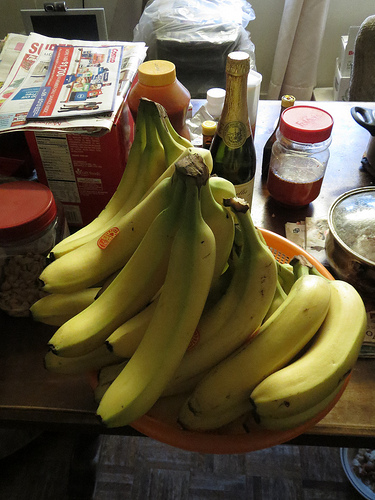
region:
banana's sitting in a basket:
[88, 191, 340, 397]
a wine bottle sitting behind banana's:
[205, 55, 254, 202]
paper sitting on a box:
[5, 87, 124, 135]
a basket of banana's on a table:
[256, 212, 361, 362]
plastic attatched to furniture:
[129, 12, 264, 55]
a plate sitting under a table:
[328, 454, 369, 494]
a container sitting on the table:
[306, 202, 360, 263]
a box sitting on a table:
[25, 139, 89, 188]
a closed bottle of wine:
[210, 51, 256, 211]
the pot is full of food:
[327, 187, 373, 286]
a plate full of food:
[337, 446, 373, 498]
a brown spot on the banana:
[280, 399, 289, 409]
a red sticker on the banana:
[96, 227, 119, 250]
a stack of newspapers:
[1, 33, 145, 135]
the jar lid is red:
[279, 105, 333, 140]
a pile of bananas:
[42, 98, 363, 428]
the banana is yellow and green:
[96, 181, 218, 424]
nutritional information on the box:
[33, 127, 81, 204]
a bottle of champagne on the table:
[215, 51, 256, 176]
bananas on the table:
[77, 124, 329, 411]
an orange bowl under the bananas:
[138, 218, 341, 443]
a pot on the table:
[327, 182, 368, 258]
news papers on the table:
[3, 30, 116, 124]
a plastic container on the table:
[0, 175, 52, 304]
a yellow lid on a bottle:
[135, 60, 180, 83]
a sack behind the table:
[132, 0, 222, 67]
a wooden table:
[0, 141, 368, 419]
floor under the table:
[114, 441, 330, 497]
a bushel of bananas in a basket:
[33, 92, 367, 449]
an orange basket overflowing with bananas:
[89, 216, 359, 455]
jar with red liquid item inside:
[263, 102, 330, 219]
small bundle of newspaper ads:
[0, 32, 150, 139]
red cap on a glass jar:
[0, 181, 57, 243]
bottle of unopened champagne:
[211, 49, 259, 215]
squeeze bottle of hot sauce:
[123, 62, 190, 150]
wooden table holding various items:
[1, 91, 369, 449]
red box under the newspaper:
[27, 58, 136, 231]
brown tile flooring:
[0, 426, 355, 495]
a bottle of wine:
[206, 48, 262, 234]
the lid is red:
[278, 108, 338, 137]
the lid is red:
[272, 96, 342, 146]